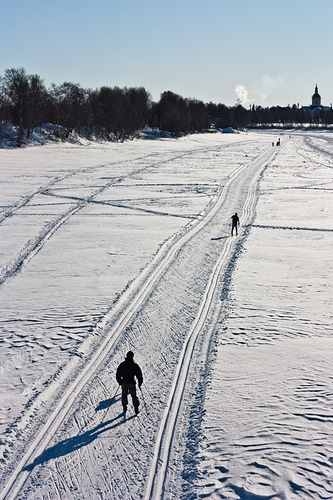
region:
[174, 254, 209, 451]
the tracks are in the snow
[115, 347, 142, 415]
a man on skis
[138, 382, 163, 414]
he is holding a ski brake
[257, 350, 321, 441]
the snow is tightly packed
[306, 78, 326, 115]
the building is pointy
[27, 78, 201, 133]
the trees are full but brown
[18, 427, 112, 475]
a shadow is reflecting off of the snow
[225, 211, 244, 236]
this man is in front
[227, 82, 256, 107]
one small puffy white cloud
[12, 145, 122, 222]
a vehicle has made these tracks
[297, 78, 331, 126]
A tall building behind the trees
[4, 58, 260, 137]
The trees are brown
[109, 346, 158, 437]
A man wearing a black jacket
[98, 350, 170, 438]
The man is holding ski poles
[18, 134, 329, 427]
A large snow covered field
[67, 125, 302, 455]
A wide track in the snow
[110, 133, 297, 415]
The people ski in the track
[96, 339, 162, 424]
The man skis in the snow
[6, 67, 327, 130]
The trees border the field of snow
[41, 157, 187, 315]
The snow is white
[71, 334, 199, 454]
a person cross country skiing.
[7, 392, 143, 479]
the shadow of a person cross country skiing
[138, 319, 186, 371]
ski tracks in the snow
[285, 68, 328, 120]
a church in the distance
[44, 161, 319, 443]
two people cross country skiing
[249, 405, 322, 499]
ridges in the snow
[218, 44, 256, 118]
smoke or steam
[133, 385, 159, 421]
a ski pole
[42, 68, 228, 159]
a cluster of trees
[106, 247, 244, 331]
tracks from a vehicle in the snow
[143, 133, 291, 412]
a road way in the snow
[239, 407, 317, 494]
a few ripples in the snow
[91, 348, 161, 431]
a man on skis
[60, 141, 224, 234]
a few tracks in the snow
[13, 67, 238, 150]
a line of trees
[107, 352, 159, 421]
a person in heavy clothing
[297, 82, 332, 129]
a distant church like building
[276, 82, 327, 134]
a building behind the trees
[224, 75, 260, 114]
a cloud of smoke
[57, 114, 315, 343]
a large snow covered field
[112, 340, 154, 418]
a person cross country skiing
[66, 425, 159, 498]
tracks from cross country skiers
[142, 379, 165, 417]
a ski pole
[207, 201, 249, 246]
a person cross country skiing in the distance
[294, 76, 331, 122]
a church in winter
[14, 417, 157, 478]
a shadow of a skier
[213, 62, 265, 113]
a pillar of smoke or steam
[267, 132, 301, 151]
people in the distance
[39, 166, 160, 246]
tracks in the snow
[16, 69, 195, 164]
deciduous trees in the winter